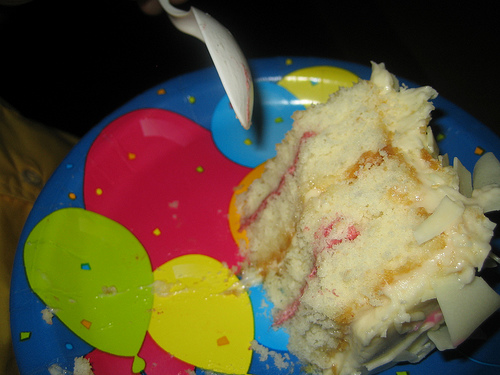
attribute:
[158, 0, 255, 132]
spoon — white, plastic, plastice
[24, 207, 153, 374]
balloon — green, yellow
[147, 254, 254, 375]
balloon — yellow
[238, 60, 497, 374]
cake — white, layered, eaten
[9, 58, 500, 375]
plate — blue, circular, disposable, colorful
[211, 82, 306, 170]
balloon — blue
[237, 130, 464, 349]
frosting — pink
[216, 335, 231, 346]
speck — orange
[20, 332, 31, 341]
speck — green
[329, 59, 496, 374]
frosting — white